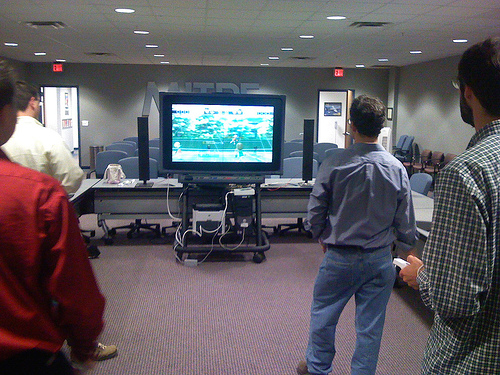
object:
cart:
[171, 174, 270, 266]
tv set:
[131, 71, 313, 204]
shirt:
[412, 117, 498, 374]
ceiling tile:
[204, 5, 263, 22]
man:
[2, 63, 106, 375]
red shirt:
[0, 160, 106, 361]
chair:
[409, 173, 432, 204]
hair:
[350, 94, 386, 139]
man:
[295, 96, 417, 373]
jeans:
[305, 245, 396, 374]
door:
[36, 83, 80, 167]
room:
[1, 0, 498, 373]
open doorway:
[316, 90, 352, 151]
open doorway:
[40, 82, 82, 154]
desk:
[77, 176, 344, 219]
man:
[399, 39, 498, 375]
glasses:
[450, 76, 465, 90]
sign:
[332, 67, 345, 78]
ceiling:
[0, 1, 495, 69]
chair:
[422, 151, 444, 174]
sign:
[52, 62, 63, 72]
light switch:
[81, 120, 89, 127]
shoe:
[80, 342, 120, 359]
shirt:
[1, 112, 84, 198]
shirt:
[308, 143, 417, 257]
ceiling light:
[298, 33, 316, 39]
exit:
[332, 66, 344, 78]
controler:
[393, 258, 412, 270]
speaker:
[134, 116, 154, 188]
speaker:
[302, 119, 315, 183]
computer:
[157, 91, 286, 184]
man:
[7, 79, 119, 360]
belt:
[327, 239, 395, 252]